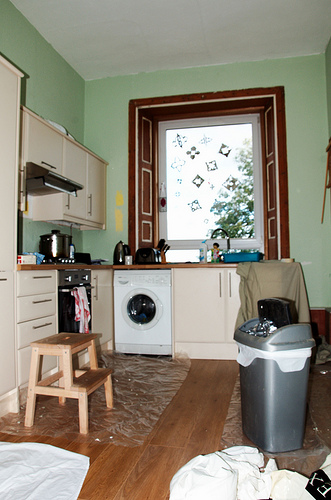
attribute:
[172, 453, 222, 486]
cloth — white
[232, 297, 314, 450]
trash can — gray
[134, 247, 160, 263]
toaster — silver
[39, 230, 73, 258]
pot — large, metal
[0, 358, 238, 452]
floor — wood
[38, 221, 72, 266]
cooker — silver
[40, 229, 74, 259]
pot — silver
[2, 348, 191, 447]
plastic — sheet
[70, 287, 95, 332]
towel — red, white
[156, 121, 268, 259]
frame — white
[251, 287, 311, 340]
garbage — full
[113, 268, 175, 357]
laundry — white, machine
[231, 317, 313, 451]
trash can — open, gray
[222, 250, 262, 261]
utility bin — blue, plastic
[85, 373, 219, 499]
wood — hard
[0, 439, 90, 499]
blanket — white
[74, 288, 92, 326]
towel — red, white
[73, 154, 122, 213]
cabinets — beige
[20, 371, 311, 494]
flooring — wooden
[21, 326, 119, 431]
step stool — light brown, wooden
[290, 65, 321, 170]
walls — mint green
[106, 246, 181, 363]
dishwasher — white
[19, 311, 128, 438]
woodenstep stool — wooden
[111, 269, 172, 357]
dryer — built-in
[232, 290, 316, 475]
trashcan — gray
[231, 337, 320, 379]
bag — white